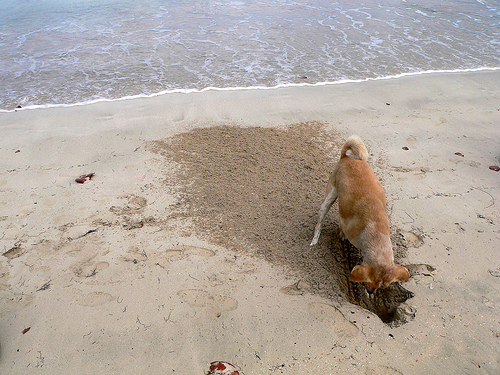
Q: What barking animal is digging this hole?
A: Dog.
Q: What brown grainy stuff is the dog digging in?
A: Sand.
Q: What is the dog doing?
A: Looking down.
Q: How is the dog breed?
A: Small.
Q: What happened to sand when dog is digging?
A: Stirred up.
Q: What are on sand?
A: Prints.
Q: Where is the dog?
A: Near beach.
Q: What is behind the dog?
A: Beach.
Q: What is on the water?
A: Foam.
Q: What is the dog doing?
A: Digging hole.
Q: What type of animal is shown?
A: Dog.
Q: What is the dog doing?
A: Digging.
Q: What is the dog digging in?
A: Sand.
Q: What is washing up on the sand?
A: Water.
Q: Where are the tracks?
A: In the sand.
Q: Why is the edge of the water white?
A: Foam.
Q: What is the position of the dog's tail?
A: Curled over the dog's back.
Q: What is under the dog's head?
A: Hole in the sand.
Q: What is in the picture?
A: A dog.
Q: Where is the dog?
A: On the beach.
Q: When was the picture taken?
A: The daytime.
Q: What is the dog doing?
A: Digging in the sand.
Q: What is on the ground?
A: Sand.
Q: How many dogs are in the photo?
A: One.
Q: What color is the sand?
A: White.